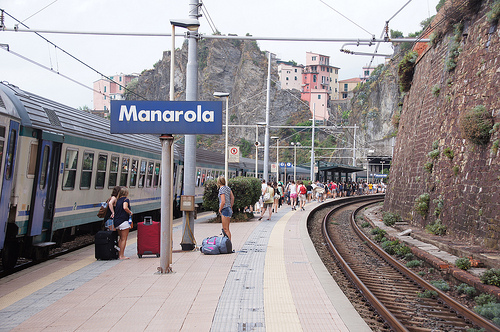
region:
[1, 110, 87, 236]
this is a train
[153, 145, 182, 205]
this is a pole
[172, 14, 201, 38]
the light is off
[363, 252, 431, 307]
these are the rails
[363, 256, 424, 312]
the rails are rusty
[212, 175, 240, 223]
this is the lady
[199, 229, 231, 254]
this is a bag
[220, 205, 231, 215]
The blue jean short shorts the lady is wearing.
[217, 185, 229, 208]
The gray shirt the girl is wearing.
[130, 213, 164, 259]
The red suitcase.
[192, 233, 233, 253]
The gray duffle bag.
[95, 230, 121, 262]
The black suitcase.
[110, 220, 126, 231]
The white shorts the woman is wearing.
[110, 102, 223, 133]
The blue sign on the pole.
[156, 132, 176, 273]
The pole the blue sign is mounted on.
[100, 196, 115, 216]
The brown bag the girl on the left is carrying.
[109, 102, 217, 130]
The word Manarola on the sign.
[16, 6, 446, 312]
the Manarola train station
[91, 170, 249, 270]
several people waiting on a train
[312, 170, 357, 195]
several people waiting on a train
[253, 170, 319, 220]
several people waiting on a train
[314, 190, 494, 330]
the rails of a train track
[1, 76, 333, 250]
a passenger train stopped at the station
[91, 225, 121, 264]
a black suitcase with wheels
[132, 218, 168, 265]
a red suit case with wheels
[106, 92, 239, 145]
a sign with the name of the train station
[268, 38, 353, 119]
buildings on a hillside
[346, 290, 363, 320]
edge fo a rak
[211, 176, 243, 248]
Someone waiting for a train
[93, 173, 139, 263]
Two people waiting for a train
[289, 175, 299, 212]
Someone waiting for a train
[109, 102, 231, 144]
A sign describing the track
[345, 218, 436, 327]
Railroad tracks for a train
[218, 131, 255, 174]
A sign about how to proceed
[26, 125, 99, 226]
A stopped train on the tracks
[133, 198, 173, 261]
A red suitcase on the ground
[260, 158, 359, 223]
People getting on a train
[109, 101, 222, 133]
blue sign with white letters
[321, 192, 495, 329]
train tracks going around a curve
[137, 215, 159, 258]
red suitcase sitting on the ground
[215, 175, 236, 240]
woman in shorts waiting to board the train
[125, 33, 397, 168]
large rock blocking the view of the city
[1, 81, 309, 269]
a passenger train waiting on the tracks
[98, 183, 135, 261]
two women waiting to get on the train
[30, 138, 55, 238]
blue door to the train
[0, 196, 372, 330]
concrete passenger loading platform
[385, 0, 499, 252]
red brick wall next to tracks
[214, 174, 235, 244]
blonde woman wearing short jean shorts